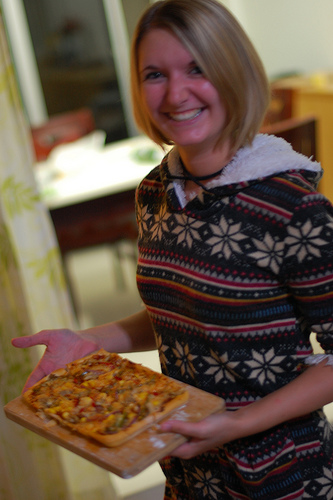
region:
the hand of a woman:
[153, 405, 246, 462]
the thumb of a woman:
[9, 323, 50, 351]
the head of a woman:
[123, 1, 269, 160]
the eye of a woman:
[141, 65, 171, 86]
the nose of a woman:
[161, 64, 193, 111]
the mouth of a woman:
[155, 103, 210, 129]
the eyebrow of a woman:
[135, 60, 162, 78]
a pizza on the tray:
[22, 346, 191, 448]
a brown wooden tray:
[0, 352, 228, 480]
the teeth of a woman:
[166, 108, 203, 120]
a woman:
[215, 231, 288, 447]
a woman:
[208, 296, 251, 464]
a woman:
[183, 301, 269, 484]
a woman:
[194, 268, 236, 494]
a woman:
[226, 297, 291, 492]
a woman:
[157, 182, 237, 418]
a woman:
[215, 351, 263, 474]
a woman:
[203, 304, 241, 418]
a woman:
[220, 315, 276, 422]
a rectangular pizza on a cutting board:
[22, 346, 189, 445]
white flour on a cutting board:
[150, 410, 184, 449]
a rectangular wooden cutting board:
[3, 349, 226, 477]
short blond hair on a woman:
[121, 1, 270, 155]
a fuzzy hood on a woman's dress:
[165, 131, 321, 207]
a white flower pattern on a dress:
[189, 464, 224, 499]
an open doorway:
[17, 0, 139, 152]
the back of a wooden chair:
[271, 112, 320, 172]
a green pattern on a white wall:
[1, 173, 43, 219]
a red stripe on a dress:
[134, 254, 281, 287]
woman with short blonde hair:
[122, 4, 284, 152]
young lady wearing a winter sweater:
[123, 4, 328, 493]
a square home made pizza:
[14, 350, 199, 450]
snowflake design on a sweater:
[125, 189, 332, 274]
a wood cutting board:
[1, 343, 222, 478]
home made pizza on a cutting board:
[0, 342, 231, 481]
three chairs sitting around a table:
[42, 79, 331, 312]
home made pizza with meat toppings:
[20, 340, 203, 455]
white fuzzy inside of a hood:
[232, 127, 325, 189]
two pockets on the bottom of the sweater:
[138, 432, 298, 499]